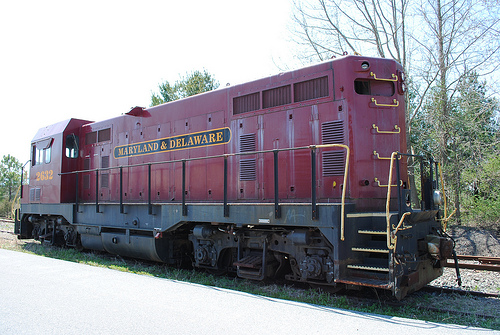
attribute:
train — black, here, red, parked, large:
[13, 56, 454, 304]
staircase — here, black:
[334, 212, 401, 290]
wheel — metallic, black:
[204, 246, 234, 275]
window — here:
[293, 75, 329, 101]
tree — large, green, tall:
[288, 0, 499, 228]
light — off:
[360, 61, 370, 72]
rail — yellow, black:
[57, 145, 351, 243]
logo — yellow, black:
[112, 126, 232, 160]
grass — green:
[0, 238, 499, 331]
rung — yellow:
[371, 96, 400, 108]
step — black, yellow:
[332, 274, 392, 289]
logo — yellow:
[35, 169, 55, 182]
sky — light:
[1, 0, 499, 184]